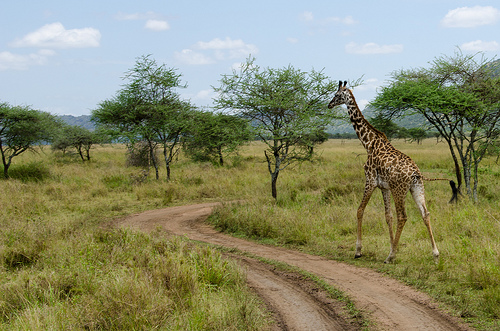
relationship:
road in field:
[118, 199, 467, 330] [2, 137, 499, 330]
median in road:
[203, 236, 367, 328] [118, 199, 467, 330]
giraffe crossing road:
[328, 78, 447, 263] [118, 199, 467, 330]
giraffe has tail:
[328, 78, 447, 263] [415, 169, 462, 203]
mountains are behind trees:
[56, 115, 106, 128] [4, 68, 326, 177]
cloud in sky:
[21, 20, 101, 49] [1, 1, 498, 108]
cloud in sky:
[184, 39, 250, 64] [1, 1, 498, 108]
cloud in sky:
[443, 6, 498, 27] [1, 1, 498, 108]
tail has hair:
[415, 169, 462, 203] [448, 178, 462, 204]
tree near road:
[229, 70, 332, 198] [118, 199, 467, 330]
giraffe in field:
[328, 78, 447, 263] [2, 137, 499, 330]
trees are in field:
[4, 68, 326, 177] [2, 137, 499, 330]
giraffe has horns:
[328, 78, 447, 263] [339, 79, 349, 86]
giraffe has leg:
[328, 78, 447, 263] [355, 185, 371, 260]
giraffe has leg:
[328, 78, 447, 263] [381, 188, 395, 253]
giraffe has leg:
[328, 78, 447, 263] [388, 181, 408, 261]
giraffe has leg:
[328, 78, 447, 263] [411, 177, 441, 261]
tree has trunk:
[229, 70, 332, 198] [268, 163, 280, 199]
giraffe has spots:
[328, 78, 447, 263] [375, 146, 396, 176]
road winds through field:
[118, 199, 467, 330] [2, 137, 499, 330]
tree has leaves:
[229, 70, 332, 198] [250, 76, 327, 112]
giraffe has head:
[328, 78, 447, 263] [328, 80, 351, 108]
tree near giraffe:
[229, 70, 332, 198] [328, 78, 447, 263]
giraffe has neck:
[328, 78, 447, 263] [346, 98, 380, 148]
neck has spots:
[346, 98, 380, 148] [356, 121, 369, 136]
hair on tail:
[448, 178, 462, 204] [415, 169, 462, 203]